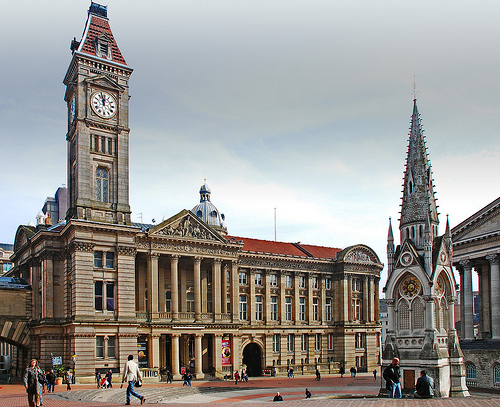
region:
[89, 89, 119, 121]
Clock high up on a tower.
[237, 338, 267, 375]
Large arched doorway in the middle of a building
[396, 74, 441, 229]
Pointy steeple on a small building to the right.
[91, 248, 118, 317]
Four windows on a building near a clock tower.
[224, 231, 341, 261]
Red section of long roof on a long building.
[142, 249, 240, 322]
5 long pillars on the upper left side of a building.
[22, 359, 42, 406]
Woman walking with a long gray buttoned coat on.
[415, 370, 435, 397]
A man sitting down near a steeple on the right.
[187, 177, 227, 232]
Dome shaped top of a building straight ahead.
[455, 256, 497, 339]
4 pillars to the right of a tall steeple on the right.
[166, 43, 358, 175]
gray sky during the day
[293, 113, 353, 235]
clouds in the sky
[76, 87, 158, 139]
white clock on top of tower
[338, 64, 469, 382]
structure with a point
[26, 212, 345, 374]
brown building with many windows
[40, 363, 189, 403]
people walking down the street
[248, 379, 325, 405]
red and gray sidewalk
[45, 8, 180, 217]
long and tall clock tower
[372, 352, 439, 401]
two people standing next to structure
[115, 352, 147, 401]
man wearing light colors walking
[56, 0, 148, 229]
clock tower on building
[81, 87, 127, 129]
clock with roman numerals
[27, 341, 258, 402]
people walking around city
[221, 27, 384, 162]
overcast blue sky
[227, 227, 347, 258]
red shingled roof on building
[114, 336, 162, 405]
man wearing blue jeans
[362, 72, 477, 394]
tall ornate monument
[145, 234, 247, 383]
tall pillars in front of building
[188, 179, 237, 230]
top of building in background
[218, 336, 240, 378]
red banner hanging on building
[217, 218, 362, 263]
red roof on the large building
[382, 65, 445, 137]
pointed steeple on the building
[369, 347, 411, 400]
man is standing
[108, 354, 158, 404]
man is walking towards the building and people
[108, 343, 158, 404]
man has a white top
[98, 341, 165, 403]
man is wearing blue jeans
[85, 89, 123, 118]
large clock on top of the building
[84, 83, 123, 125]
roman numerals on the clock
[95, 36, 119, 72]
vent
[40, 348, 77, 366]
white sign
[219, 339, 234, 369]
red banner on building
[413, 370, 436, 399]
Man wearing black leather jacket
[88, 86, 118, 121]
White clock on tower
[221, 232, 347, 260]
red roof on building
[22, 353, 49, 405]
woman in gray coat walking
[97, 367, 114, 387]
Person pushing red stroller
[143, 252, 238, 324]
5 columns on a building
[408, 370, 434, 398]
man sitting on steps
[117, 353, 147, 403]
Man walking on brick street